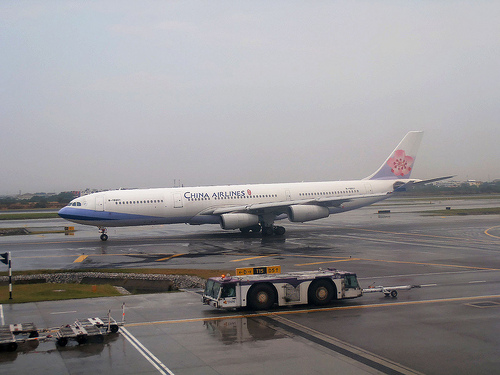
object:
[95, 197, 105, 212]
door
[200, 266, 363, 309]
truck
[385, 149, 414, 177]
flower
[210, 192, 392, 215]
plane wing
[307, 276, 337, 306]
wheel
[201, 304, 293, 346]
reflection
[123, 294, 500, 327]
mark lines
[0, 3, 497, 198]
sky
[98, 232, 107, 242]
landing gear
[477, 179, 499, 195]
trees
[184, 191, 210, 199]
writing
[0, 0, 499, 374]
airport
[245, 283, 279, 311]
wheel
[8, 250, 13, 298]
pole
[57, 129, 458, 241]
plane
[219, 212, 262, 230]
jet engine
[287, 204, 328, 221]
jet engine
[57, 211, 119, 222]
line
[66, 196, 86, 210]
cockpit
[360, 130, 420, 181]
vertical stabilizer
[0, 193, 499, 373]
ground